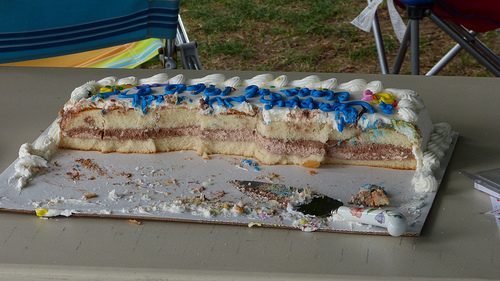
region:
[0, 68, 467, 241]
Cake is on a cardboard sheet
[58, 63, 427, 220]
The cake is half eaten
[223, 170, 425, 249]
A cake cutter is in the foreground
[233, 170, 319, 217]
Cake cutter has frosting on it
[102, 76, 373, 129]
Words on the cake are written in blue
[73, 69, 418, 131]
The frosting on the cake is white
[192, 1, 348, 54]
Grass is on the ground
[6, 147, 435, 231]
Cardboard sheet is white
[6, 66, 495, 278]
The table is white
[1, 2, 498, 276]
Photo was taken outdoors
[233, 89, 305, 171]
a cake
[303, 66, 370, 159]
a cake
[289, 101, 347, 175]
a cake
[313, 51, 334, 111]
a cake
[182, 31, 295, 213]
a cake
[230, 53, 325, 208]
a cake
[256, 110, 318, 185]
a cake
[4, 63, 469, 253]
half eaten cake on a board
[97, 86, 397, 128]
blue frosting on a cake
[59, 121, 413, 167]
chocolate filling in a cake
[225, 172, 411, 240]
cake knife covered in cake and frosting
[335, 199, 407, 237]
decorated handle of a cake knife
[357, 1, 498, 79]
fold up picnic chair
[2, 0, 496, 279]
outside scene with a cake on a table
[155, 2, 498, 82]
grass behind a picnic table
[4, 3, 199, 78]
picnic chair in front of a table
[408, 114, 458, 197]
white frosting piped around the base of a cake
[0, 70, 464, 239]
half of a birthday cake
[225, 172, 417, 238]
silver knife with a colorful floral handle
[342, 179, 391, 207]
colorful crumb of cake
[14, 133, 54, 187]
white icing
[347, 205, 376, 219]
pink floral design on a knife handle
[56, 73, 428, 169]
blue icing on half of a birthday cake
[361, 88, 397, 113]
pink yellow and blue icing on a birthday cake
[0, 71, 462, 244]
half a birthday cake on white piece of cardboard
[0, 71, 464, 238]
birthday cake on a white table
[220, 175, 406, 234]
knife covered in cake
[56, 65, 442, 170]
a long birthday cake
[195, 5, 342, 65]
some grass and dirt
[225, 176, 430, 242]
a sharp birthday knife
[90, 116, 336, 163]
the layer of a cake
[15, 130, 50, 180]
white birthday cake frosting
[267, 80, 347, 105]
blue birthday cake frosting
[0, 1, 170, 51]
some blue chair fabric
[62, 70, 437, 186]
a birthday cake that has been cut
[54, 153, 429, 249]
some frosting and a knife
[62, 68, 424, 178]
a delicious cake